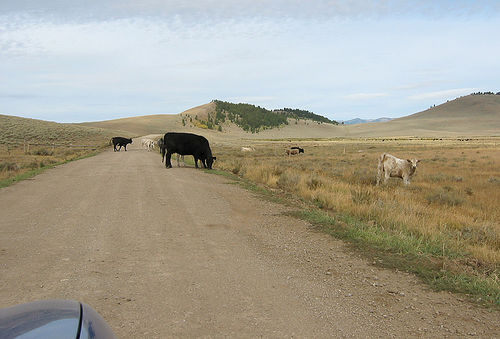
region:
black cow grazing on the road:
[160, 128, 220, 173]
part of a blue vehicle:
[3, 292, 108, 332]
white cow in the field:
[367, 146, 429, 191]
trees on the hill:
[212, 95, 287, 137]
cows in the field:
[284, 142, 309, 162]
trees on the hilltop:
[457, 81, 498, 100]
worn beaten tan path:
[92, 177, 177, 268]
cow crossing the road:
[102, 130, 137, 155]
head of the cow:
[202, 153, 222, 173]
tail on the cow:
[160, 139, 164, 164]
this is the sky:
[218, 12, 373, 98]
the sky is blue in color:
[314, 35, 389, 67]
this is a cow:
[161, 127, 214, 172]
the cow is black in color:
[168, 130, 203, 148]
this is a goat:
[376, 145, 421, 178]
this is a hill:
[193, 94, 262, 126]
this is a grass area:
[380, 223, 447, 278]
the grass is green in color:
[368, 223, 394, 250]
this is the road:
[86, 220, 258, 306]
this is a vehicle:
[15, 299, 90, 337]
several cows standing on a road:
[43, 111, 238, 202]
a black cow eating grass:
[156, 121, 228, 181]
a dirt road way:
[2, 100, 290, 281]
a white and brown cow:
[362, 137, 427, 195]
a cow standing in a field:
[345, 126, 464, 231]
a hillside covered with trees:
[196, 99, 348, 148]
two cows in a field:
[283, 134, 333, 185]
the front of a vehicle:
[37, 283, 126, 338]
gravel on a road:
[258, 277, 440, 314]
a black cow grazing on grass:
[151, 132, 227, 180]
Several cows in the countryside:
[106, 130, 416, 183]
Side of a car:
[0, 297, 106, 334]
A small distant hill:
[400, 92, 498, 118]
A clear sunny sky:
[0, 80, 499, 120]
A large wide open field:
[155, 130, 498, 307]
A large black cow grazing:
[160, 130, 212, 166]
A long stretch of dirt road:
[0, 138, 496, 334]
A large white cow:
[375, 152, 415, 184]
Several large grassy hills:
[0, 92, 499, 142]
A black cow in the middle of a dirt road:
[110, 136, 132, 149]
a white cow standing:
[373, 149, 421, 189]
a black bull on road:
[151, 125, 218, 184]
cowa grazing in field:
[232, 128, 447, 203]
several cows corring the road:
[55, 95, 226, 191]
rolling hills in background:
[0, 93, 498, 139]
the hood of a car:
[0, 284, 132, 336]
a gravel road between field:
[8, 217, 317, 285]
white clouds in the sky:
[1, 1, 178, 82]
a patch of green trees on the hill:
[196, 93, 301, 131]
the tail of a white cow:
[334, 148, 399, 173]